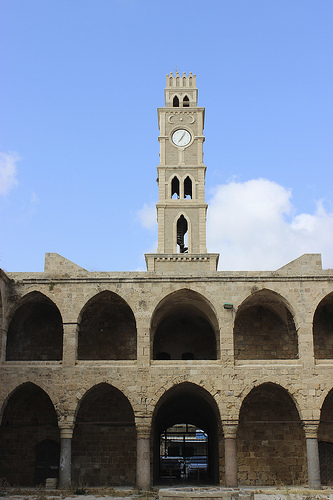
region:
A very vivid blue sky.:
[58, 54, 128, 133]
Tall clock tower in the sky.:
[140, 60, 209, 273]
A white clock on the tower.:
[166, 119, 194, 151]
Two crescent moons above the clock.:
[163, 110, 197, 129]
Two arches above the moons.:
[167, 89, 193, 108]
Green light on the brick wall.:
[218, 296, 244, 318]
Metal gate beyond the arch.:
[156, 416, 209, 484]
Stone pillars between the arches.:
[133, 422, 151, 496]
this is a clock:
[159, 123, 197, 157]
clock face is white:
[163, 121, 202, 152]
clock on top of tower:
[150, 66, 220, 271]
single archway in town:
[163, 203, 197, 261]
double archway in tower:
[164, 162, 194, 198]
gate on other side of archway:
[159, 415, 227, 486]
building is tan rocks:
[2, 257, 330, 492]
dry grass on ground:
[15, 473, 322, 497]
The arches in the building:
[7, 381, 321, 495]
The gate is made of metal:
[157, 424, 208, 472]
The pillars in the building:
[50, 436, 326, 492]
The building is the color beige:
[28, 291, 318, 476]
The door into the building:
[30, 437, 64, 489]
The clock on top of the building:
[168, 122, 193, 150]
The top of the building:
[160, 66, 202, 107]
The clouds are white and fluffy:
[218, 186, 290, 259]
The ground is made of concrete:
[33, 476, 140, 499]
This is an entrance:
[149, 275, 225, 365]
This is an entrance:
[74, 289, 145, 371]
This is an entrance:
[1, 289, 74, 363]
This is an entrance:
[225, 285, 305, 359]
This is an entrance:
[3, 384, 66, 491]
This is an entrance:
[75, 386, 145, 480]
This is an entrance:
[146, 383, 228, 495]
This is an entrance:
[234, 376, 314, 489]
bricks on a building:
[130, 313, 154, 403]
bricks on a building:
[119, 299, 170, 393]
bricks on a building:
[131, 315, 173, 377]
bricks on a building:
[121, 240, 181, 370]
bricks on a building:
[139, 333, 148, 383]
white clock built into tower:
[167, 125, 193, 149]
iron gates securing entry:
[151, 417, 218, 484]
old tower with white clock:
[142, 62, 220, 270]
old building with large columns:
[0, 64, 332, 499]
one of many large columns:
[56, 420, 76, 489]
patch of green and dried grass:
[0, 477, 157, 498]